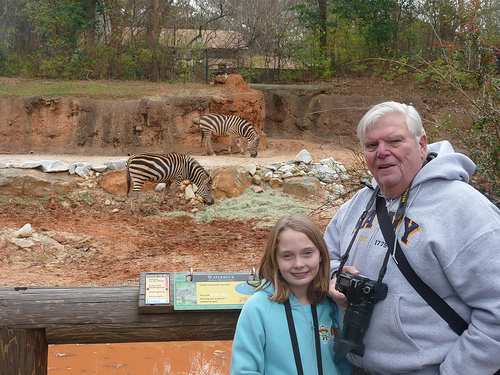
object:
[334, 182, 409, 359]
camera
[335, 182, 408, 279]
strap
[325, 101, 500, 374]
man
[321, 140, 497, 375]
sweat shirt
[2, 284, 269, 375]
fence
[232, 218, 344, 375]
girl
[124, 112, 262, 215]
zebras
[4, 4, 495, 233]
zoo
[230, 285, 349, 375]
sweatshirt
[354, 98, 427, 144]
hair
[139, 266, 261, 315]
sign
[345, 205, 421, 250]
lettering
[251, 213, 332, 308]
hair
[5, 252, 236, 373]
water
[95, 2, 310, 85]
trees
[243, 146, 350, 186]
pile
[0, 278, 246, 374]
round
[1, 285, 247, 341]
railing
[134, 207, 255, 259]
hay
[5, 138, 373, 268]
ground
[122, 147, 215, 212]
zebra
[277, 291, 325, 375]
strap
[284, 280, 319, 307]
neck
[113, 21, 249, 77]
building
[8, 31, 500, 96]
distance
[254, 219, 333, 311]
length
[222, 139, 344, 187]
rocks